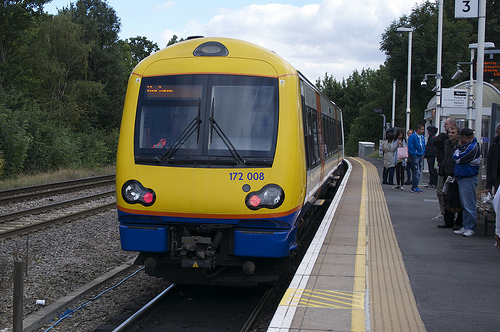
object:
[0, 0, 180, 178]
trees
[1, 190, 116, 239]
tracks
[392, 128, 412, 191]
woman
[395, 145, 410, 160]
pink bag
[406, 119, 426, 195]
man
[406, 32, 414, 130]
pole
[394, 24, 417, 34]
lights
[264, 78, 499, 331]
station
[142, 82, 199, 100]
window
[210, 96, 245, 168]
windshield wipers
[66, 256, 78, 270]
gravel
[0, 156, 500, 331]
ground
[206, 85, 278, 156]
windows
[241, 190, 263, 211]
headlights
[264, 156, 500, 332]
sidewalk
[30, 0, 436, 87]
sky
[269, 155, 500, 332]
platform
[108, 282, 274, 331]
tracks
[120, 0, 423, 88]
cloud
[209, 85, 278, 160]
windshield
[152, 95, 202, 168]
wipers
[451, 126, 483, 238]
people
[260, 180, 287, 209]
headlight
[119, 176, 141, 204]
headlight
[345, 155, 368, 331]
stripe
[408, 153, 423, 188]
blue jeans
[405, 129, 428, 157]
blue jacket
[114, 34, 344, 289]
train